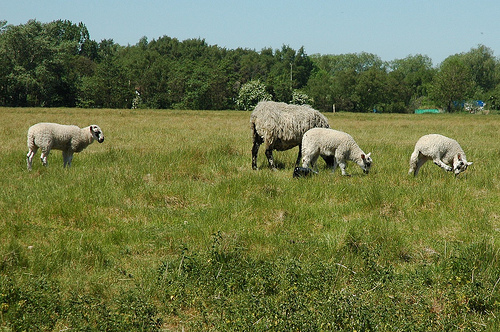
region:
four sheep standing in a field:
[32, 74, 474, 215]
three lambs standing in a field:
[13, 114, 477, 182]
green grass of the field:
[162, 198, 404, 295]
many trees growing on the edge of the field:
[17, 26, 403, 112]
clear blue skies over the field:
[288, 5, 407, 38]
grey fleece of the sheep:
[267, 104, 317, 133]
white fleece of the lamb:
[38, 118, 80, 147]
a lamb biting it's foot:
[401, 125, 475, 182]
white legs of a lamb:
[16, 145, 81, 173]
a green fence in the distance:
[412, 105, 447, 119]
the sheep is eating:
[290, 133, 395, 197]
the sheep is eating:
[287, 118, 361, 188]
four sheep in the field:
[0, 75, 484, 221]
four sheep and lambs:
[23, 98, 478, 178]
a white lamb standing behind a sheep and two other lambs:
[23, 120, 104, 162]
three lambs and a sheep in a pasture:
[24, 98, 471, 178]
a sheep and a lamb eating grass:
[249, 98, 376, 176]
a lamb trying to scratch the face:
[406, 133, 473, 176]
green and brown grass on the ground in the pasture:
[12, 176, 493, 233]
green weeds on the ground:
[1, 229, 498, 329]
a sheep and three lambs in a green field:
[25, 96, 472, 176]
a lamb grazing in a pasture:
[298, 125, 376, 177]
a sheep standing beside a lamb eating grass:
[249, 98, 374, 175]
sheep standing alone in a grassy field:
[23, 121, 105, 168]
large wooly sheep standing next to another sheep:
[249, 98, 329, 171]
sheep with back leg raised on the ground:
[406, 133, 474, 177]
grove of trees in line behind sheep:
[0, 17, 498, 113]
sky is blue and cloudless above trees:
[0, 1, 498, 71]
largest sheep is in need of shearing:
[250, 98, 332, 170]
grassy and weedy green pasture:
[1, 106, 495, 330]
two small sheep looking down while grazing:
[298, 125, 474, 176]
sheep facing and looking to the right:
[25, 120, 107, 165]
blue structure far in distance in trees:
[449, 94, 485, 109]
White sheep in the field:
[26, 90, 133, 170]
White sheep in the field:
[400, 107, 467, 193]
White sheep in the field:
[291, 128, 389, 193]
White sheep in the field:
[243, 81, 341, 181]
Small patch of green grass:
[16, 274, 81, 326]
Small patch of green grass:
[74, 247, 150, 327]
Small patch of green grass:
[147, 249, 227, 311]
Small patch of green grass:
[207, 225, 264, 285]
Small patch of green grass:
[252, 244, 307, 296]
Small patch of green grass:
[302, 239, 371, 296]